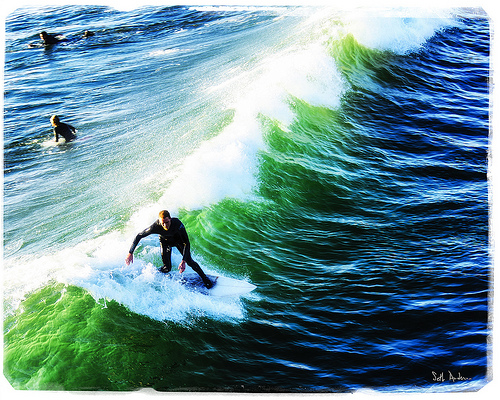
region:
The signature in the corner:
[425, 361, 477, 386]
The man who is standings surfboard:
[144, 258, 257, 298]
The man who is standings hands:
[122, 248, 191, 275]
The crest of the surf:
[194, 0, 434, 192]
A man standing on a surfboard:
[117, 210, 222, 304]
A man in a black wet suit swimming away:
[34, 21, 92, 51]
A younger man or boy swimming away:
[47, 109, 78, 149]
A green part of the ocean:
[12, 290, 151, 390]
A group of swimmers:
[22, 26, 249, 309]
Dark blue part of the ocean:
[377, 209, 447, 384]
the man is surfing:
[72, 181, 229, 311]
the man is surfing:
[102, 178, 301, 367]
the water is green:
[188, 144, 282, 276]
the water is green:
[52, 300, 192, 385]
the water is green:
[219, 144, 372, 228]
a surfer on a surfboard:
[125, 209, 215, 289]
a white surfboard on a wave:
[168, 271, 257, 297]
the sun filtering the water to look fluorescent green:
[192, 34, 382, 255]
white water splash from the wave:
[249, 35, 319, 105]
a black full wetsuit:
[129, 220, 212, 286]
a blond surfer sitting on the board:
[39, 114, 89, 147]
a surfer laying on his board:
[27, 26, 92, 51]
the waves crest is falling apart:
[166, 34, 328, 202]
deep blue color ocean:
[344, 188, 490, 398]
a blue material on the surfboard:
[175, 273, 219, 289]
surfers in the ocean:
[23, 20, 223, 302]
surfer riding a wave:
[123, 206, 260, 306]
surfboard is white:
[154, 257, 265, 303]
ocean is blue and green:
[8, 3, 490, 390]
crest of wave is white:
[8, 15, 451, 347]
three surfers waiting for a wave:
[23, 15, 111, 165]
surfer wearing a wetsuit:
[122, 198, 217, 295]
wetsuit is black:
[122, 211, 217, 293]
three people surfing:
[12, 8, 483, 380]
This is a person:
[121, 203, 231, 311]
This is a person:
[41, 108, 88, 155]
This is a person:
[30, 22, 72, 59]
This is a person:
[78, 18, 100, 39]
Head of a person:
[149, 203, 178, 229]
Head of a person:
[46, 108, 64, 130]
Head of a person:
[36, 23, 55, 46]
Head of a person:
[78, 20, 93, 40]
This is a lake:
[195, 72, 289, 191]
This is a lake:
[26, 251, 109, 366]